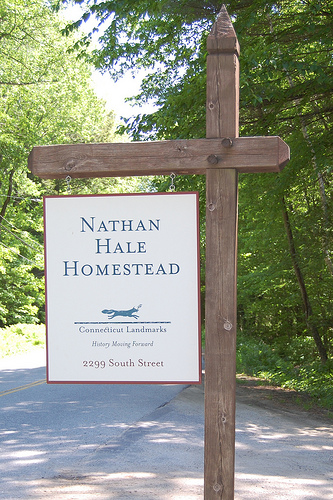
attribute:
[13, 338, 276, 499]
road — dirty, cracked, clear, shadowy, marked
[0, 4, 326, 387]
trees — leafy, green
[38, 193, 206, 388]
sign — white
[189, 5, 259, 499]
post — knotted, wooden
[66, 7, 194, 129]
sky — blue